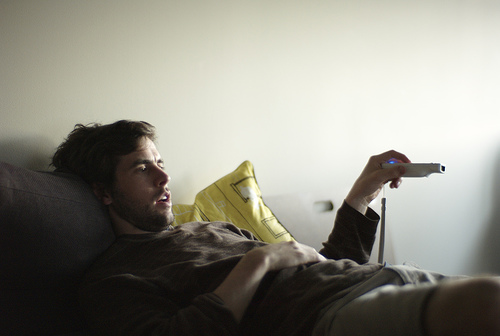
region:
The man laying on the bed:
[51, 119, 499, 334]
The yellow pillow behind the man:
[170, 160, 297, 242]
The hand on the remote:
[344, 149, 412, 214]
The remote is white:
[381, 161, 446, 178]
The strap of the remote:
[377, 198, 386, 267]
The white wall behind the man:
[0, 0, 499, 276]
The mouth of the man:
[155, 190, 173, 207]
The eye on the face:
[133, 165, 148, 176]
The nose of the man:
[152, 163, 170, 187]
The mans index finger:
[376, 148, 411, 165]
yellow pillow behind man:
[165, 152, 297, 250]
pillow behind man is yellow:
[163, 154, 303, 251]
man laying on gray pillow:
[1, 155, 121, 335]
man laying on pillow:
[2, 152, 129, 325]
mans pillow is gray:
[0, 159, 128, 335]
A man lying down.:
[63, 144, 196, 321]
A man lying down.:
[113, 145, 253, 330]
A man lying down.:
[130, 240, 234, 326]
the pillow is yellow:
[212, 158, 319, 242]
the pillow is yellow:
[240, 175, 275, 233]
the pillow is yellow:
[215, 158, 300, 305]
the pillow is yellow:
[182, 144, 326, 325]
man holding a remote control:
[34, 102, 459, 328]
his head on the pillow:
[6, 113, 221, 268]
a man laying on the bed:
[39, 116, 499, 334]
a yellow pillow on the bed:
[177, 157, 301, 249]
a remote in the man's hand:
[389, 155, 441, 179]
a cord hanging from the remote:
[381, 195, 387, 261]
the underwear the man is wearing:
[331, 253, 441, 334]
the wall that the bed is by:
[4, 5, 490, 267]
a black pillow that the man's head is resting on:
[8, 164, 103, 311]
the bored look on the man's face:
[98, 125, 173, 225]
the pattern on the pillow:
[232, 171, 287, 241]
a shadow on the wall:
[474, 159, 499, 295]